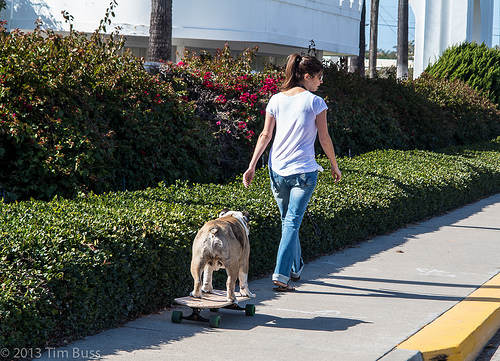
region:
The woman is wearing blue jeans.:
[268, 164, 299, 276]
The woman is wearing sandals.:
[272, 266, 297, 293]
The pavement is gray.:
[345, 288, 390, 322]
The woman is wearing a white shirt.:
[267, 89, 328, 176]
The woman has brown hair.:
[279, 48, 325, 90]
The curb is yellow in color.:
[441, 312, 478, 331]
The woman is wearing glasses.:
[279, 51, 324, 91]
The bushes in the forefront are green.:
[76, 231, 163, 274]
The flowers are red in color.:
[231, 71, 258, 113]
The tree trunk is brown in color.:
[148, 3, 171, 57]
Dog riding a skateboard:
[165, 205, 261, 357]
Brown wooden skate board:
[164, 275, 273, 355]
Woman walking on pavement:
[238, 33, 349, 323]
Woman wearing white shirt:
[255, 33, 333, 335]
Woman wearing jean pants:
[247, 29, 322, 306]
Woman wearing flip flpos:
[250, 40, 315, 317]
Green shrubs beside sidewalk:
[166, 172, 297, 312]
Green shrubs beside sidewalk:
[325, 146, 434, 250]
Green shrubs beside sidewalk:
[348, 49, 499, 208]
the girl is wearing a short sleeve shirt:
[266, 89, 327, 174]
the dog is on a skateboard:
[183, 206, 255, 316]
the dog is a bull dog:
[187, 203, 253, 299]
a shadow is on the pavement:
[197, 305, 362, 330]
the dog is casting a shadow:
[183, 206, 355, 333]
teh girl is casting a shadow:
[288, 266, 495, 309]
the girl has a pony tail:
[281, 51, 303, 86]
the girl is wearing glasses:
[315, 73, 324, 80]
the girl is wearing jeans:
[266, 169, 317, 280]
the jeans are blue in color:
[268, 170, 316, 283]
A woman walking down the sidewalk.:
[246, 40, 358, 305]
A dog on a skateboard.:
[169, 183, 254, 333]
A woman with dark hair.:
[271, 38, 329, 100]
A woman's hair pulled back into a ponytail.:
[280, 41, 330, 99]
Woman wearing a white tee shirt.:
[261, 48, 331, 177]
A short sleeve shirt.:
[249, 84, 332, 179]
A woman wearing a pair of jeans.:
[254, 53, 336, 298]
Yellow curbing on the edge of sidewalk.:
[403, 270, 498, 358]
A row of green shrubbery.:
[1, 150, 497, 327]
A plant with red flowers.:
[163, 43, 281, 170]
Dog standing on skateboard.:
[165, 205, 264, 330]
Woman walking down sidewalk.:
[236, 44, 344, 294]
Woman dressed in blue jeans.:
[264, 165, 321, 283]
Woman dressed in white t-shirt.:
[260, 85, 334, 180]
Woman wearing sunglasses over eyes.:
[307, 66, 329, 88]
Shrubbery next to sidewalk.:
[346, 138, 498, 240]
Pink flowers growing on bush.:
[168, 47, 277, 178]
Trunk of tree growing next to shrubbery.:
[142, 0, 185, 71]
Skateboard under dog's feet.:
[167, 285, 257, 330]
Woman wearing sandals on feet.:
[268, 261, 310, 301]